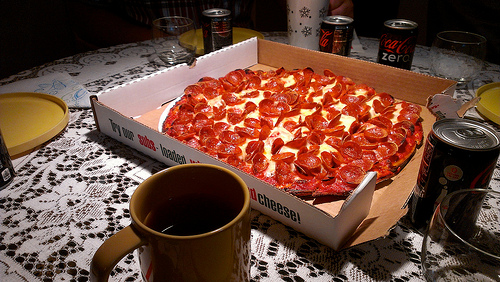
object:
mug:
[85, 161, 254, 281]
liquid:
[161, 217, 234, 236]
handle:
[88, 224, 144, 282]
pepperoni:
[239, 90, 260, 99]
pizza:
[160, 66, 425, 198]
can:
[406, 117, 499, 243]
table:
[0, 30, 500, 282]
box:
[88, 35, 483, 252]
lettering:
[245, 184, 302, 226]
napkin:
[0, 71, 93, 108]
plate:
[0, 92, 70, 158]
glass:
[151, 15, 199, 65]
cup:
[286, 0, 330, 52]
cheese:
[338, 114, 358, 133]